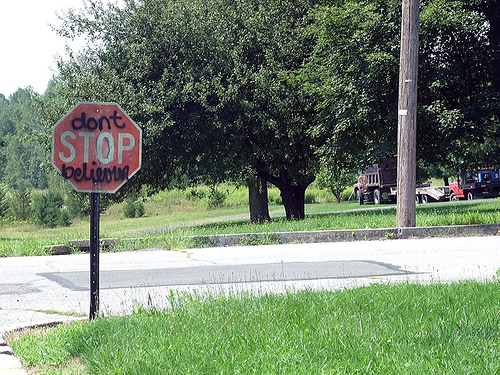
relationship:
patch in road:
[37, 257, 428, 295] [1, 238, 500, 323]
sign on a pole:
[50, 102, 144, 197] [90, 196, 100, 316]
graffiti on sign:
[65, 113, 132, 180] [50, 102, 144, 197]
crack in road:
[1, 298, 84, 322] [1, 238, 500, 323]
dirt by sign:
[53, 353, 91, 375] [50, 102, 144, 197]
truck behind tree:
[353, 161, 399, 206] [48, 2, 499, 221]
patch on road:
[37, 257, 428, 295] [1, 238, 500, 323]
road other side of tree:
[134, 199, 498, 231] [48, 2, 499, 221]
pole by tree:
[398, 0, 421, 228] [48, 2, 499, 221]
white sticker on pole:
[396, 107, 410, 116] [398, 0, 421, 228]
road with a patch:
[1, 238, 500, 323] [37, 257, 428, 295]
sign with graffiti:
[50, 102, 144, 197] [65, 113, 132, 180]